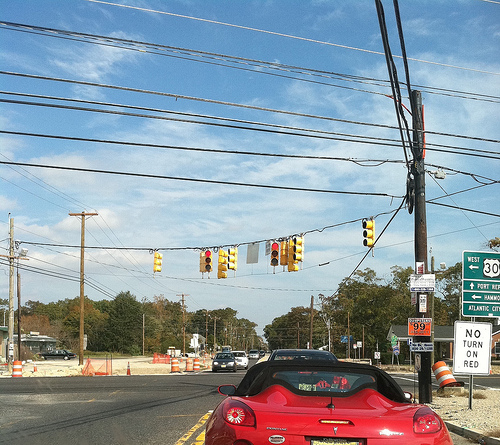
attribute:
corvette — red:
[371, 376, 406, 395]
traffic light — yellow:
[201, 250, 211, 271]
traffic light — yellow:
[227, 247, 236, 270]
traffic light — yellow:
[361, 218, 376, 248]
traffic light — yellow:
[152, 250, 163, 268]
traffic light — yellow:
[291, 235, 305, 262]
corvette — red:
[207, 378, 457, 443]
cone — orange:
[192, 355, 201, 371]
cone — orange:
[168, 357, 183, 372]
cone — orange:
[431, 356, 464, 388]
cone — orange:
[11, 358, 25, 375]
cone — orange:
[183, 357, 193, 372]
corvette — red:
[207, 357, 448, 444]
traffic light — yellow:
[143, 238, 175, 276]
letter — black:
[465, 329, 471, 336]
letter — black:
[460, 339, 467, 347]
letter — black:
[473, 330, 480, 337]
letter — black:
[466, 340, 473, 346]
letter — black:
[472, 341, 477, 348]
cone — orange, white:
[170, 356, 181, 373]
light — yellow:
[240, 215, 332, 285]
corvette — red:
[217, 349, 459, 444]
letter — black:
[459, 358, 471, 370]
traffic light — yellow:
[152, 250, 162, 272]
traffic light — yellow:
[197, 248, 211, 275]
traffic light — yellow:
[213, 242, 227, 279]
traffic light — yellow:
[266, 235, 279, 267]